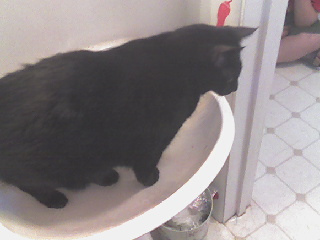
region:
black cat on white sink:
[6, 42, 207, 190]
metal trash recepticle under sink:
[165, 183, 218, 238]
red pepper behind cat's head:
[210, 0, 232, 26]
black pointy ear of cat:
[225, 22, 260, 34]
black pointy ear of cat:
[219, 42, 238, 53]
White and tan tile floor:
[239, 66, 309, 224]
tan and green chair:
[280, 5, 319, 51]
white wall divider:
[206, 4, 270, 217]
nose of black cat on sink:
[227, 77, 248, 95]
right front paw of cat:
[126, 158, 159, 185]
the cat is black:
[9, 21, 244, 179]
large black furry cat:
[22, 34, 237, 160]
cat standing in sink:
[41, 41, 253, 208]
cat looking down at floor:
[56, 23, 267, 122]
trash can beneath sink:
[170, 195, 216, 236]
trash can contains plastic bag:
[171, 193, 216, 238]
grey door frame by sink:
[232, 1, 293, 236]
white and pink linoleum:
[274, 96, 319, 231]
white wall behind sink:
[9, 3, 166, 81]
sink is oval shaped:
[6, 47, 266, 239]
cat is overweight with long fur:
[91, 50, 199, 147]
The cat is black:
[5, 19, 276, 209]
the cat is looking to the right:
[174, 16, 251, 108]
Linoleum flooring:
[215, 51, 318, 237]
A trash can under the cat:
[138, 182, 221, 238]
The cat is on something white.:
[11, 10, 226, 233]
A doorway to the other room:
[239, 0, 289, 222]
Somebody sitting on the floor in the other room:
[256, 0, 315, 79]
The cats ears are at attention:
[213, 16, 264, 71]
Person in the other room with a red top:
[285, 0, 318, 16]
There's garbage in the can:
[151, 178, 220, 238]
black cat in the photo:
[2, 29, 263, 181]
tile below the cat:
[270, 157, 307, 208]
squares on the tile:
[269, 108, 310, 165]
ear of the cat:
[234, 14, 263, 41]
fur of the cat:
[61, 93, 115, 134]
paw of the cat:
[129, 165, 173, 206]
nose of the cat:
[226, 75, 250, 96]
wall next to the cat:
[45, 8, 77, 29]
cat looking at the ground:
[0, 35, 259, 197]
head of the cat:
[194, 24, 268, 105]